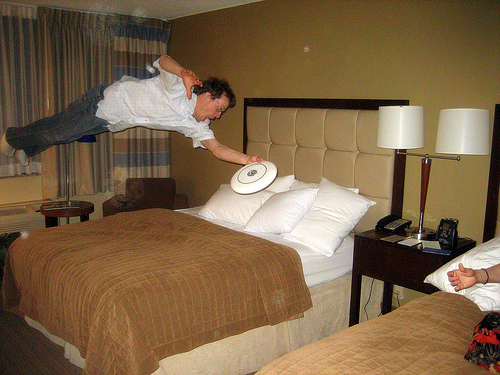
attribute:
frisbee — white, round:
[231, 165, 291, 196]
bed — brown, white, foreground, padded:
[12, 164, 350, 335]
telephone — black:
[357, 179, 438, 253]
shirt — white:
[88, 73, 215, 142]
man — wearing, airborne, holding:
[0, 36, 246, 190]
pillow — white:
[240, 174, 382, 265]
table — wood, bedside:
[322, 208, 480, 301]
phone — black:
[364, 195, 429, 243]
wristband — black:
[172, 57, 209, 74]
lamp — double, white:
[350, 71, 498, 173]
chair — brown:
[70, 134, 193, 219]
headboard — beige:
[218, 78, 437, 195]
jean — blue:
[17, 77, 138, 154]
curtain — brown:
[10, 6, 170, 97]